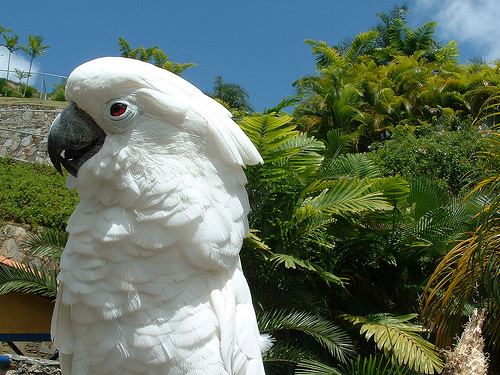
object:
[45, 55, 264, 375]
parrot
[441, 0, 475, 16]
clouds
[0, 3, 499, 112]
sky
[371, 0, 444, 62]
tree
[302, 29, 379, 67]
tree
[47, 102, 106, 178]
beak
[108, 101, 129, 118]
eye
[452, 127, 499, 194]
bushes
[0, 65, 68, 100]
fence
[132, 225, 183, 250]
feathers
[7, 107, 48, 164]
wall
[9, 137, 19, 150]
stone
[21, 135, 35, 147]
stone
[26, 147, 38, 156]
stone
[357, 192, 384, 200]
leaves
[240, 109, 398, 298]
palm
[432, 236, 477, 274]
leaves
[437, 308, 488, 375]
straw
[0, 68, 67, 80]
rail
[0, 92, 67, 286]
hillside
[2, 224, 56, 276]
wall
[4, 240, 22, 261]
rock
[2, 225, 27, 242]
rock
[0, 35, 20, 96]
palm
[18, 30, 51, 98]
palm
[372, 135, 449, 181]
bushes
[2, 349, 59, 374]
ladder